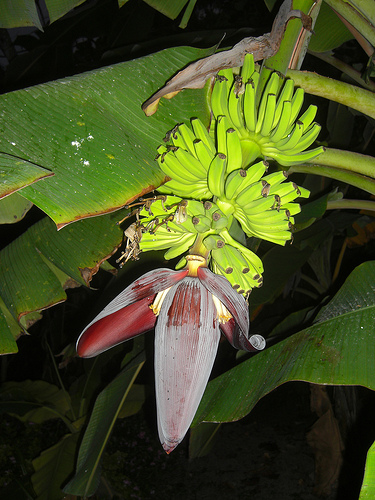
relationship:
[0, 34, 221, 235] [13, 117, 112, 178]
leaf has spots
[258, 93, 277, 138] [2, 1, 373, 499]
banana attached to tree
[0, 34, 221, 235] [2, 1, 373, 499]
leaf covers landscape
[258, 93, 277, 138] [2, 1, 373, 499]
banana on tree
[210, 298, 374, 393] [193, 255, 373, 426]
vein on leaf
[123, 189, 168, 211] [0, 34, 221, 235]
twig on leaf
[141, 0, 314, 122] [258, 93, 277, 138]
bird on banana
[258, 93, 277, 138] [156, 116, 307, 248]
banana in bushel